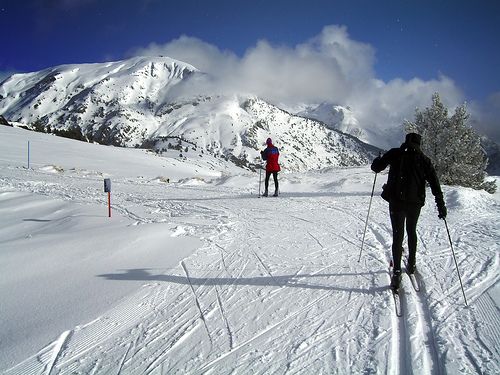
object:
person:
[371, 132, 449, 293]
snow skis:
[389, 247, 420, 318]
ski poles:
[357, 172, 471, 308]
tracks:
[357, 214, 442, 375]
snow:
[0, 55, 500, 375]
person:
[259, 138, 281, 198]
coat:
[261, 144, 282, 171]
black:
[369, 146, 447, 270]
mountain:
[0, 54, 389, 176]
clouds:
[130, 20, 499, 151]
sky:
[0, 0, 500, 147]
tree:
[401, 90, 500, 195]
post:
[103, 177, 111, 217]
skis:
[262, 190, 279, 197]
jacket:
[371, 142, 449, 219]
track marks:
[0, 167, 500, 375]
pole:
[27, 141, 30, 169]